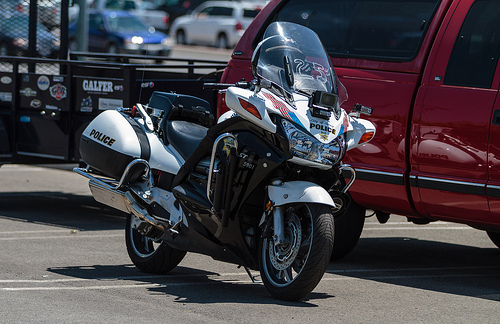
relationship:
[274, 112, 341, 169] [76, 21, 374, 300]
headlight on bike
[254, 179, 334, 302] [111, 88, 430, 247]
front tire of motorcycle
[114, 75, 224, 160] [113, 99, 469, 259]
seat on motorcycle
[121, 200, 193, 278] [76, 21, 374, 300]
tire on bike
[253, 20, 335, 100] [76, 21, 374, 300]
windshield on bike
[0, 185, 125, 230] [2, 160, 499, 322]
shadow on road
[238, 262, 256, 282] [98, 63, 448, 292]
kickstand of motorcycle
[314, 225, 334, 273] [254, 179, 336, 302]
tread on front tire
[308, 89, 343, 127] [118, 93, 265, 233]
lights on motorcycle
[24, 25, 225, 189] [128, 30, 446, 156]
trailer on truck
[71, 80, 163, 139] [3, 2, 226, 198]
sticker on trailer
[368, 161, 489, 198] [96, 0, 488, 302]
trim on truck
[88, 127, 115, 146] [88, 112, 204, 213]
word on motorcycle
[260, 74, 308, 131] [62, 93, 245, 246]
american flags on mototcycle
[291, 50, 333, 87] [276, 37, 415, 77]
25 on window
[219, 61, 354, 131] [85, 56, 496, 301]
helmet on bike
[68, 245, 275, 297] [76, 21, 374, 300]
shadow of bike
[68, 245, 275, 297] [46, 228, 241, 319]
shadow on street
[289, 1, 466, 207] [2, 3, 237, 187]
truck pulling trailer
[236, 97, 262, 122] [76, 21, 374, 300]
lights on bike